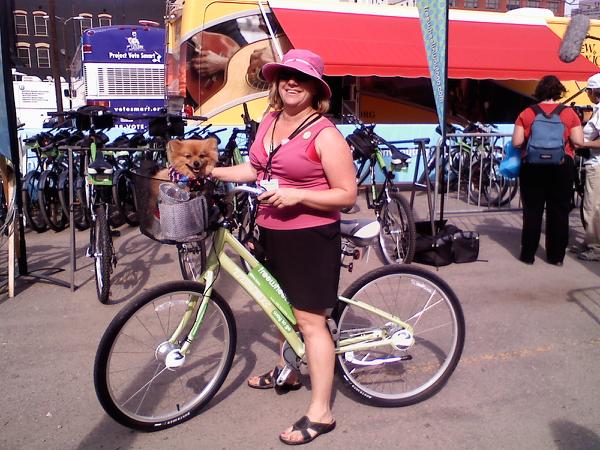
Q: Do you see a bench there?
A: No, there are no benches.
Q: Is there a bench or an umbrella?
A: No, there are no benches or umbrellas.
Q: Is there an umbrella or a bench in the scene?
A: No, there are no benches or umbrellas.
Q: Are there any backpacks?
A: Yes, there is a backpack.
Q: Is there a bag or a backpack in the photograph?
A: Yes, there is a backpack.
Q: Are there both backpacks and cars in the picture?
A: No, there is a backpack but no cars.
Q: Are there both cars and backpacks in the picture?
A: No, there is a backpack but no cars.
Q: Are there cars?
A: No, there are no cars.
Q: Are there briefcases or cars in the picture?
A: No, there are no cars or briefcases.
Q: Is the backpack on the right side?
A: Yes, the backpack is on the right of the image.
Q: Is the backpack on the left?
A: No, the backpack is on the right of the image.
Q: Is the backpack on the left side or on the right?
A: The backpack is on the right of the image.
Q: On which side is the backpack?
A: The backpack is on the right of the image.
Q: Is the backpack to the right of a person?
A: No, the backpack is to the left of a person.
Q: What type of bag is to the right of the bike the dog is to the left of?
A: The bag is a backpack.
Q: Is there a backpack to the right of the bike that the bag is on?
A: Yes, there is a backpack to the right of the bike.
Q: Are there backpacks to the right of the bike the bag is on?
A: Yes, there is a backpack to the right of the bike.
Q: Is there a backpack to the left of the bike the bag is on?
A: No, the backpack is to the right of the bike.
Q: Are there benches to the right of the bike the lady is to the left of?
A: No, there is a backpack to the right of the bike.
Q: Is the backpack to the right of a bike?
A: Yes, the backpack is to the right of a bike.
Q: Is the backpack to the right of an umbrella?
A: No, the backpack is to the right of a bike.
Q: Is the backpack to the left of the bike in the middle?
A: No, the backpack is to the right of the bike.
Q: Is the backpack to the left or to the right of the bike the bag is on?
A: The backpack is to the right of the bike.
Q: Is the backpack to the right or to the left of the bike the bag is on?
A: The backpack is to the right of the bike.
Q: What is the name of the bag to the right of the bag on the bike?
A: The bag is a backpack.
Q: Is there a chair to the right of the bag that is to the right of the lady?
A: No, there is a backpack to the right of the bag.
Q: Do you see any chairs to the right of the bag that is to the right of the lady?
A: No, there is a backpack to the right of the bag.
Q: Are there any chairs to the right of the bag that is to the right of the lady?
A: No, there is a backpack to the right of the bag.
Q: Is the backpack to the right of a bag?
A: Yes, the backpack is to the right of a bag.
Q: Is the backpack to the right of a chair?
A: No, the backpack is to the right of a bag.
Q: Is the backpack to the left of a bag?
A: No, the backpack is to the right of a bag.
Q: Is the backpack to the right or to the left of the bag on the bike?
A: The backpack is to the right of the bag.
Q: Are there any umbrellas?
A: No, there are no umbrellas.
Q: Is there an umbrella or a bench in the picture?
A: No, there are no umbrellas or benches.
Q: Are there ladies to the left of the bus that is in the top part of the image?
A: No, the lady is to the right of the bus.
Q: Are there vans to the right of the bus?
A: No, there is a lady to the right of the bus.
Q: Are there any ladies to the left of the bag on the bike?
A: Yes, there is a lady to the left of the bag.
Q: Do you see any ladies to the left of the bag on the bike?
A: Yes, there is a lady to the left of the bag.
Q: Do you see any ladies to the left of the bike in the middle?
A: Yes, there is a lady to the left of the bike.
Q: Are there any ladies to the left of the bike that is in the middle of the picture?
A: Yes, there is a lady to the left of the bike.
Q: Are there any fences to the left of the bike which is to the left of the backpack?
A: No, there is a lady to the left of the bike.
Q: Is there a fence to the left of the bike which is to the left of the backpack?
A: No, there is a lady to the left of the bike.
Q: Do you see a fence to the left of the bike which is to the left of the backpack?
A: No, there is a lady to the left of the bike.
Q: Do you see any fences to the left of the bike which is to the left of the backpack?
A: No, there is a lady to the left of the bike.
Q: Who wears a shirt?
A: The lady wears a shirt.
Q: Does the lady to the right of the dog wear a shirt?
A: Yes, the lady wears a shirt.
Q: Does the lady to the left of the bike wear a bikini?
A: No, the lady wears a shirt.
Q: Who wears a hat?
A: The lady wears a hat.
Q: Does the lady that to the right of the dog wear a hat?
A: Yes, the lady wears a hat.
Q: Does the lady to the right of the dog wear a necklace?
A: No, the lady wears a hat.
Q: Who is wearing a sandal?
A: The lady is wearing a sandal.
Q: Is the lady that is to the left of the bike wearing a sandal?
A: Yes, the lady is wearing a sandal.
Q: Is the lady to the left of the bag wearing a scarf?
A: No, the lady is wearing a sandal.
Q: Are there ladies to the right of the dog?
A: Yes, there is a lady to the right of the dog.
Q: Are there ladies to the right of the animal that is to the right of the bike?
A: Yes, there is a lady to the right of the dog.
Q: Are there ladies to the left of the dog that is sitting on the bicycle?
A: No, the lady is to the right of the dog.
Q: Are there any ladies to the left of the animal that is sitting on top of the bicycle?
A: No, the lady is to the right of the dog.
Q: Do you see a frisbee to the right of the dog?
A: No, there is a lady to the right of the dog.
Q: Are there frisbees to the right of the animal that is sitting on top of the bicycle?
A: No, there is a lady to the right of the dog.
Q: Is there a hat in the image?
A: Yes, there is a hat.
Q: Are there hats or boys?
A: Yes, there is a hat.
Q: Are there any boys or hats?
A: Yes, there is a hat.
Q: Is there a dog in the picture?
A: Yes, there is a dog.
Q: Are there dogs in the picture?
A: Yes, there is a dog.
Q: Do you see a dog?
A: Yes, there is a dog.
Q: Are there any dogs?
A: Yes, there is a dog.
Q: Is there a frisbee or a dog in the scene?
A: Yes, there is a dog.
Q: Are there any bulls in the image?
A: No, there are no bulls.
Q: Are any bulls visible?
A: No, there are no bulls.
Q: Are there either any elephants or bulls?
A: No, there are no bulls or elephants.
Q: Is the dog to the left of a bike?
A: No, the dog is to the right of a bike.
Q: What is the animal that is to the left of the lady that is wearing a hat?
A: The animal is a dog.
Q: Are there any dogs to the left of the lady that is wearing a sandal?
A: Yes, there is a dog to the left of the lady.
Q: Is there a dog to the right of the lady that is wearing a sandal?
A: No, the dog is to the left of the lady.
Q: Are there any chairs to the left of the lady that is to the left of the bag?
A: No, there is a dog to the left of the lady.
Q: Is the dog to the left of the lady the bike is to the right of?
A: Yes, the dog is to the left of the lady.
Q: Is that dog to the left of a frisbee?
A: No, the dog is to the left of the lady.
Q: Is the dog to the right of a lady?
A: No, the dog is to the left of a lady.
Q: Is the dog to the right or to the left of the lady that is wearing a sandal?
A: The dog is to the left of the lady.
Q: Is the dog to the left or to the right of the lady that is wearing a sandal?
A: The dog is to the left of the lady.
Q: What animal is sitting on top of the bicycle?
A: The dog is sitting on top of the bicycle.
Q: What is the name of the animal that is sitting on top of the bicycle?
A: The animal is a dog.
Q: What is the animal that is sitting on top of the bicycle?
A: The animal is a dog.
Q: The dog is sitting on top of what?
A: The dog is sitting on top of the bicycle.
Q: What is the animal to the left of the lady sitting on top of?
A: The dog is sitting on top of the bicycle.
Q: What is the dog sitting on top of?
A: The dog is sitting on top of the bicycle.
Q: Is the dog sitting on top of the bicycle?
A: Yes, the dog is sitting on top of the bicycle.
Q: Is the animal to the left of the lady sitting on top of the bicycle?
A: Yes, the dog is sitting on top of the bicycle.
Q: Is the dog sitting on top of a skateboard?
A: No, the dog is sitting on top of the bicycle.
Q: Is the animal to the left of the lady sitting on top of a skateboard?
A: No, the dog is sitting on top of the bicycle.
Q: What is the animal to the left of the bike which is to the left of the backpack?
A: The animal is a dog.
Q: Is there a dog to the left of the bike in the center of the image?
A: Yes, there is a dog to the left of the bike.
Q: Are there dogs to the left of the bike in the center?
A: Yes, there is a dog to the left of the bike.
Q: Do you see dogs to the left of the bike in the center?
A: Yes, there is a dog to the left of the bike.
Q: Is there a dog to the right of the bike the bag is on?
A: No, the dog is to the left of the bike.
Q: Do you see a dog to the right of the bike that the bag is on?
A: No, the dog is to the left of the bike.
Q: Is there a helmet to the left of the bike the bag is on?
A: No, there is a dog to the left of the bike.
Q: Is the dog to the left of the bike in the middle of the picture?
A: Yes, the dog is to the left of the bike.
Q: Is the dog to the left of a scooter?
A: No, the dog is to the left of the bike.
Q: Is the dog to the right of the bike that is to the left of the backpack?
A: No, the dog is to the left of the bike.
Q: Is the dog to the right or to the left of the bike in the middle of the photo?
A: The dog is to the left of the bike.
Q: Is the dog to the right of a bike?
A: Yes, the dog is to the right of a bike.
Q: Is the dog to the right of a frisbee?
A: No, the dog is to the right of a bike.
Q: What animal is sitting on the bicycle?
A: The dog is sitting on the bicycle.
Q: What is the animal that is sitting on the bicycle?
A: The animal is a dog.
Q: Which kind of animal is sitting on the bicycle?
A: The animal is a dog.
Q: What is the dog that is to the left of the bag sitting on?
A: The dog is sitting on the bicycle.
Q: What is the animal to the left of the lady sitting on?
A: The dog is sitting on the bicycle.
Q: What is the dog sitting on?
A: The dog is sitting on the bicycle.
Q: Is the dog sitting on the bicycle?
A: Yes, the dog is sitting on the bicycle.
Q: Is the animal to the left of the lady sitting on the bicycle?
A: Yes, the dog is sitting on the bicycle.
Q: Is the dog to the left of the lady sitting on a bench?
A: No, the dog is sitting on the bicycle.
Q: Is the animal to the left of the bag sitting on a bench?
A: No, the dog is sitting on the bicycle.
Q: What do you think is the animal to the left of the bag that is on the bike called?
A: The animal is a dog.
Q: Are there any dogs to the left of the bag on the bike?
A: Yes, there is a dog to the left of the bag.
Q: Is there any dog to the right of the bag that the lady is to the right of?
A: No, the dog is to the left of the bag.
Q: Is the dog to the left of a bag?
A: Yes, the dog is to the left of a bag.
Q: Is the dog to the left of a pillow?
A: No, the dog is to the left of a bag.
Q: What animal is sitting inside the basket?
A: The dog is sitting inside the basket.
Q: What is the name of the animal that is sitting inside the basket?
A: The animal is a dog.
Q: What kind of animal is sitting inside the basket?
A: The animal is a dog.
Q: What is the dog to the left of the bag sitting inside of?
A: The dog is sitting inside the basket.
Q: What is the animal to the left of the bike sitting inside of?
A: The dog is sitting inside the basket.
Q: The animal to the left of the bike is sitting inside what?
A: The dog is sitting inside the basket.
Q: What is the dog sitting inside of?
A: The dog is sitting inside the basket.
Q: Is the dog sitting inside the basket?
A: Yes, the dog is sitting inside the basket.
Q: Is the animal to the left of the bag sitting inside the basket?
A: Yes, the dog is sitting inside the basket.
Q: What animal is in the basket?
A: The animal is a dog.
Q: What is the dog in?
A: The dog is in the basket.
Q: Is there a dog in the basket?
A: Yes, there is a dog in the basket.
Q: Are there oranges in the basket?
A: No, there is a dog in the basket.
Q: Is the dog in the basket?
A: Yes, the dog is in the basket.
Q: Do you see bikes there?
A: Yes, there is a bike.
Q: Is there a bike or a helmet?
A: Yes, there is a bike.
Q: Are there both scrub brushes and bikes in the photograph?
A: No, there is a bike but no scrub brushes.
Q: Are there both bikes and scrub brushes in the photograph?
A: No, there is a bike but no scrub brushes.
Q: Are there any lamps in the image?
A: No, there are no lamps.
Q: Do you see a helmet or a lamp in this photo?
A: No, there are no lamps or helmets.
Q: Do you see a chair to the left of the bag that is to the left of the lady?
A: No, there is a bike to the left of the bag.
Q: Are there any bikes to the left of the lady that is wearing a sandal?
A: Yes, there is a bike to the left of the lady.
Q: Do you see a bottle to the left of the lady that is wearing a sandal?
A: No, there is a bike to the left of the lady.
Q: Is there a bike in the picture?
A: Yes, there is a bike.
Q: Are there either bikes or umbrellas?
A: Yes, there is a bike.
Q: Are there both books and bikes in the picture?
A: No, there is a bike but no books.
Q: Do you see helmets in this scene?
A: No, there are no helmets.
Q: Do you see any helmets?
A: No, there are no helmets.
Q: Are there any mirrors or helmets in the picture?
A: No, there are no helmets or mirrors.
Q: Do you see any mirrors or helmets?
A: No, there are no helmets or mirrors.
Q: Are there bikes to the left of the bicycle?
A: Yes, there is a bike to the left of the bicycle.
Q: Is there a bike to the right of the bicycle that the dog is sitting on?
A: No, the bike is to the left of the bicycle.